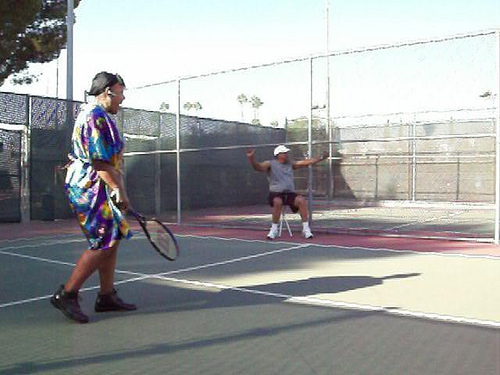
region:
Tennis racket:
[109, 189, 179, 264]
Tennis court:
[3, 227, 499, 373]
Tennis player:
[50, 70, 180, 325]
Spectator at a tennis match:
[240, 142, 328, 240]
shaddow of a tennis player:
[81, 271, 421, 323]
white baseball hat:
[273, 145, 288, 154]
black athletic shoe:
[94, 285, 135, 312]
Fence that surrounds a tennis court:
[4, 27, 498, 240]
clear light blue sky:
[3, 0, 499, 127]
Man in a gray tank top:
[245, 142, 328, 239]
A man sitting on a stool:
[240, 132, 333, 247]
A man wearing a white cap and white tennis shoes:
[244, 143, 336, 253]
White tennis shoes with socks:
[262, 215, 319, 248]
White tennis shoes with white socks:
[254, 206, 316, 260]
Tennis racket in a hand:
[105, 181, 198, 266]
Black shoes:
[25, 276, 150, 329]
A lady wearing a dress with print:
[50, 53, 132, 265]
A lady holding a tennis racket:
[72, 55, 192, 275]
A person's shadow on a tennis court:
[204, 238, 483, 374]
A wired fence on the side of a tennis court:
[333, 107, 493, 249]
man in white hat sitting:
[245, 145, 330, 240]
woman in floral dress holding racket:
[47, 71, 175, 323]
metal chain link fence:
[310, 58, 408, 138]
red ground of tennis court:
[354, 232, 414, 247]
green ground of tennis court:
[437, 266, 484, 304]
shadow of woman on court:
[220, 262, 425, 308]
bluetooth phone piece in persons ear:
[104, 89, 123, 99]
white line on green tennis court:
[254, 243, 312, 259]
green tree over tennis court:
[0, 0, 83, 74]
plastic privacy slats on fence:
[32, 105, 52, 178]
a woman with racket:
[53, 48, 199, 325]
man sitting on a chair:
[222, 106, 344, 261]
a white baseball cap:
[271, 144, 293, 157]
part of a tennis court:
[2, 198, 497, 374]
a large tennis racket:
[108, 192, 187, 264]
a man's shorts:
[266, 185, 301, 213]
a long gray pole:
[64, 0, 88, 166]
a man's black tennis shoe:
[52, 278, 94, 323]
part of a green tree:
[0, 0, 83, 97]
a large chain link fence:
[83, 27, 498, 243]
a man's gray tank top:
[263, 157, 298, 189]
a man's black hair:
[86, 70, 126, 98]